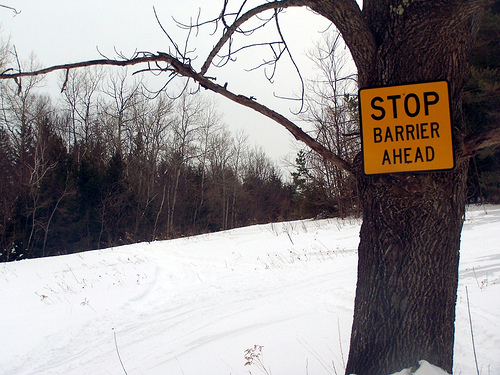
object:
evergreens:
[0, 135, 137, 257]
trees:
[158, 99, 201, 236]